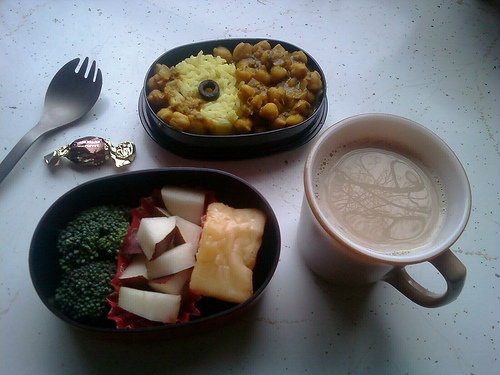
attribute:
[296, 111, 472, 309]
cup — white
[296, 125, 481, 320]
mug — brown, white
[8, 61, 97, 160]
spork — metal, plastic, gray, black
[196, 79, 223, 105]
olive — black, sliced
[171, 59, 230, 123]
rice — white, cooked, yellow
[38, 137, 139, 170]
candy — brown, yellow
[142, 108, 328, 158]
dish — round, plastic, black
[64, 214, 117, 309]
vegetables — green, pieces, cooked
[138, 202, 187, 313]
potato — sliced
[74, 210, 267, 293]
food — hot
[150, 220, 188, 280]
apple — white, cut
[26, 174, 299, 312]
bowl — black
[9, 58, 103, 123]
spork — gray, plastic, grey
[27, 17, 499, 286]
table — white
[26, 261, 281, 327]
tin — black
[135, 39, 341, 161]
container — oval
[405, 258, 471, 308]
handle — tan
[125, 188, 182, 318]
fruit — sliced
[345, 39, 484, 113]
dots — black